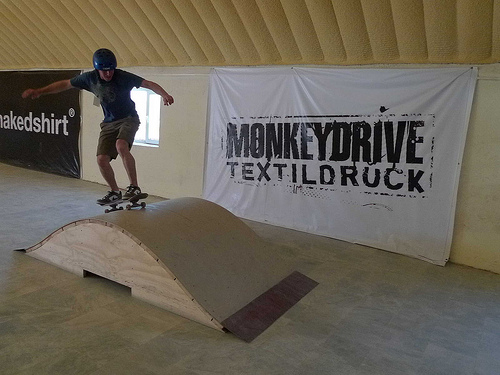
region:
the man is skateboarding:
[20, 31, 187, 218]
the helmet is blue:
[80, 34, 119, 91]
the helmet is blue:
[79, 41, 127, 89]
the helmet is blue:
[83, 34, 115, 79]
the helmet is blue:
[83, 37, 130, 87]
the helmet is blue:
[76, 41, 133, 96]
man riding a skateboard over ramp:
[17, 15, 354, 352]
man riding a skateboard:
[42, 18, 192, 225]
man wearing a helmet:
[87, 36, 119, 74]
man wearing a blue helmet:
[82, 45, 129, 83]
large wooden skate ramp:
[48, 165, 318, 372]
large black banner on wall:
[2, 63, 96, 178]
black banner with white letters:
[4, 71, 92, 178]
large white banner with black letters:
[200, 51, 484, 253]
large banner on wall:
[195, 49, 493, 300]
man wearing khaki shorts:
[74, 108, 164, 163]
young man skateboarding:
[17, 43, 176, 211]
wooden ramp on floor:
[0, 194, 329, 324]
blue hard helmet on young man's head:
[90, 48, 117, 82]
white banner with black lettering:
[203, 62, 485, 242]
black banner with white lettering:
[0, 60, 80, 175]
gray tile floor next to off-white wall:
[323, 233, 497, 373]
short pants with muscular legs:
[92, 116, 147, 206]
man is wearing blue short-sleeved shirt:
[71, 70, 141, 122]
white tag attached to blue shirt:
[90, 90, 101, 110]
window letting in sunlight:
[128, 85, 165, 147]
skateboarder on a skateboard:
[19, 43, 175, 215]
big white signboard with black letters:
[202, 66, 478, 263]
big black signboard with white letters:
[0, 65, 81, 187]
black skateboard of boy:
[98, 188, 147, 213]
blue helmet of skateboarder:
[92, 46, 116, 74]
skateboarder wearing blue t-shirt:
[25, 46, 175, 218]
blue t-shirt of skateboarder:
[67, 71, 147, 121]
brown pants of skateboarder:
[95, 107, 140, 159]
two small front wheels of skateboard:
[124, 196, 148, 213]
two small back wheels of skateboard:
[102, 202, 122, 217]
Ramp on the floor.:
[17, 188, 321, 343]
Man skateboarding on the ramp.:
[30, 31, 175, 216]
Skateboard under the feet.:
[101, 188, 155, 217]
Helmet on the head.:
[89, 45, 123, 86]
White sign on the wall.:
[195, 60, 485, 267]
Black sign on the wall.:
[1, 64, 86, 186]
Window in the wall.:
[125, 82, 171, 152]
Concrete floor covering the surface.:
[1, 153, 496, 373]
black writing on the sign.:
[222, 102, 439, 200]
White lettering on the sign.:
[0, 102, 80, 144]